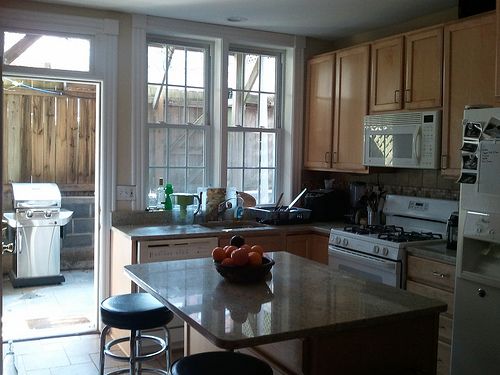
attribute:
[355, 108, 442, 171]
microwave — white, overhead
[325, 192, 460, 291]
range — white, gas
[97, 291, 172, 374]
stool — round, leather, black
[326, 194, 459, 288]
stove — white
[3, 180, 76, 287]
outdoor grill — stainless steel, silver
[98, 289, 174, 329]
cushion — black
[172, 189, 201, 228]
water pitcher — brita, green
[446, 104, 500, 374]
refrigerator — white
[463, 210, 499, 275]
icemaker — ice, dispenser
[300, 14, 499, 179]
cabinets — light brown, wooden, wood, brown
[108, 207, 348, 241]
counter top — granite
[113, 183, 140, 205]
switchplate — white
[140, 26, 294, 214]
window — open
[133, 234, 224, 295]
dishwasher — white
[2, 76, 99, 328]
door — open